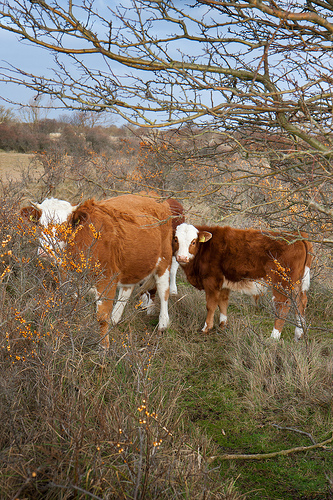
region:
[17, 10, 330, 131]
branches coming off of a tree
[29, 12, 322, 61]
the sky through the tree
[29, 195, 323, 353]
two cows in the grass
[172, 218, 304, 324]
a smaller brown cow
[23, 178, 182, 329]
a larger brown cow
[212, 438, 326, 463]
a stick on the ground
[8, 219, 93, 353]
red leaves on a bush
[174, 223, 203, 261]
a cow with a white stripe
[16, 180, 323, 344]
two cows standing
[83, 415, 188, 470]
many sticks on a bush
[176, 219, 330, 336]
a brown and white calf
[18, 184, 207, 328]
a brown and white mother cow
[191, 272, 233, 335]
the small hooves of a baby cow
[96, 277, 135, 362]
the long legs of a mother cow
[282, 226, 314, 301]
a baby cows short tail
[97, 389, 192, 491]
small yellow flowers beginning to bloom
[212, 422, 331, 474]
a stick laying on the ground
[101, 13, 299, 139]
branches of a tree without leaves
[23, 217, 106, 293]
wild flowers blowing on a tree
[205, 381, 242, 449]
a small patch of green grass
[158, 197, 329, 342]
small cow standing on grass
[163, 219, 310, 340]
brown and white cow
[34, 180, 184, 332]
brown and white cow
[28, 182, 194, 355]
small cow standing on grass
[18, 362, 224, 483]
dry vegetation in front of cows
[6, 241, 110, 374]
dry vegetation in front of cows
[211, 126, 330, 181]
skinny bare tree branch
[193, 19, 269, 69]
skinny bare tree branch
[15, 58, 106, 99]
skinny bare tree branch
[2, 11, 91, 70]
skinny bare tree branch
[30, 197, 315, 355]
the cowss are two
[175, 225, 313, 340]
the calf is brown and white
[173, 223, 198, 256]
the face is white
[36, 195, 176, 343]
the cow is brown and white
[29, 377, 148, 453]
the branches are grey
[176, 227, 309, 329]
the calf is looking at the camera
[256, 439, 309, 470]
twig is on the ground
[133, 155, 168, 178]
the flowers are orange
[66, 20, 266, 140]
the branches are full of thorns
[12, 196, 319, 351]
the cows are looking at the camera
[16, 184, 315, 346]
two cows in a field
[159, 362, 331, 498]
not a lot of grass in this area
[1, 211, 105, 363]
tiny yellow-orange flowers on this bush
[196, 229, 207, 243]
the cow's ear has an ID tag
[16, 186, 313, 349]
little cow is a darker brown than big cow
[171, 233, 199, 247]
little cow has gentle eyes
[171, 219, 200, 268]
little cow has a mostly white face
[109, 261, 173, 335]
big cow's back legs are white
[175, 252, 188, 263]
little cow has a pink nose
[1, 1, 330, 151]
the tree has no leaves